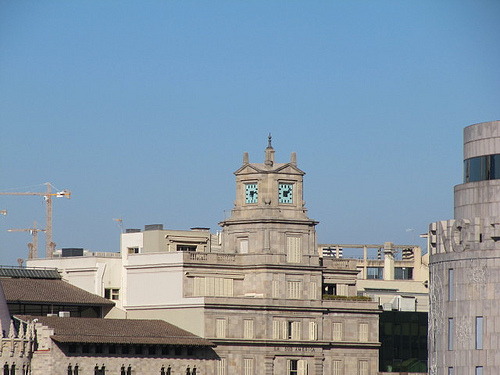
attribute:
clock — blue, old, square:
[241, 180, 262, 205]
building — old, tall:
[124, 134, 378, 373]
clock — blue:
[275, 179, 296, 206]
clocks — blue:
[241, 178, 297, 207]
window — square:
[236, 235, 251, 256]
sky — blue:
[3, 2, 499, 265]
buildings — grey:
[2, 121, 498, 375]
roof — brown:
[12, 314, 218, 349]